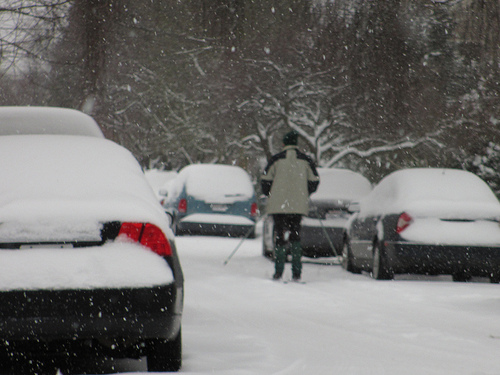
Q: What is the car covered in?
A: Snow.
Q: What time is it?
A: Evening.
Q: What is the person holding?
A: Poles.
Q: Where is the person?
A: Outside somewhere.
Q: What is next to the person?
A: A car.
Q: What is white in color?
A: The snow.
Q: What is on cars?
A: Snow.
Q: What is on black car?
A: Snow.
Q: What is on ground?
A: White snow.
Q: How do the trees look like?
A: Covered with snow.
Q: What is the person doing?
A: Skiing.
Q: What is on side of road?
A: Cars.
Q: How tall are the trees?
A: Very tall.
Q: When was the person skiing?
A: During winter time.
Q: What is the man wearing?
A: Black top.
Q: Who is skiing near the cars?
A: A man.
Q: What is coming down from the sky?
A: Snowflakes.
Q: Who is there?
A: Man.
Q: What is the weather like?
A: Snowing.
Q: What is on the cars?
A: Snow.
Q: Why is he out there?
A: Skiing.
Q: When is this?
A: Late afternoon.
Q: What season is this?
A: Wintertime.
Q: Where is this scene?
A: Street scene.